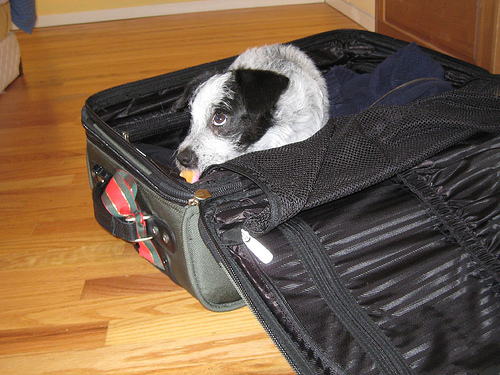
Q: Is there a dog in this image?
A: Yes, there is a dog.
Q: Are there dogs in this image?
A: Yes, there is a dog.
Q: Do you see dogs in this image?
A: Yes, there is a dog.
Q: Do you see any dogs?
A: Yes, there is a dog.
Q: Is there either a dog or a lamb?
A: Yes, there is a dog.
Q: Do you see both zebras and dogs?
A: No, there is a dog but no zebras.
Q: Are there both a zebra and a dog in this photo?
A: No, there is a dog but no zebras.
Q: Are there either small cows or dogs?
A: Yes, there is a small dog.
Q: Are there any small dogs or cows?
A: Yes, there is a small dog.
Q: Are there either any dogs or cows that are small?
A: Yes, the dog is small.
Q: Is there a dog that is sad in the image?
A: Yes, there is a sad dog.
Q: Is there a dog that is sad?
A: Yes, there is a dog that is sad.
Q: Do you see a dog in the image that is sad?
A: Yes, there is a dog that is sad.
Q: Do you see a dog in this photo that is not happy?
A: Yes, there is a sad dog.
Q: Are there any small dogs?
A: Yes, there is a small dog.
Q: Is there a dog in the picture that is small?
A: Yes, there is a dog that is small.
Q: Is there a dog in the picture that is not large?
A: Yes, there is a small dog.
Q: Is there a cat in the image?
A: No, there are no cats.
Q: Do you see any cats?
A: No, there are no cats.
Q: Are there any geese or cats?
A: No, there are no cats or geese.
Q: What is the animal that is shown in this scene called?
A: The animal is a dog.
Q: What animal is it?
A: The animal is a dog.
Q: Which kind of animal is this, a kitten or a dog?
A: That is a dog.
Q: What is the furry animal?
A: The animal is a dog.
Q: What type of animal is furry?
A: The animal is a dog.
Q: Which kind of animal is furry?
A: The animal is a dog.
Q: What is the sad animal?
A: The animal is a dog.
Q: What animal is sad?
A: The animal is a dog.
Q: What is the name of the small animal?
A: The animal is a dog.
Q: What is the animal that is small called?
A: The animal is a dog.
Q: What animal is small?
A: The animal is a dog.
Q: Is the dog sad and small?
A: Yes, the dog is sad and small.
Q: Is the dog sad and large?
A: No, the dog is sad but small.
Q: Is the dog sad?
A: Yes, the dog is sad.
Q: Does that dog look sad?
A: Yes, the dog is sad.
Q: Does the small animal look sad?
A: Yes, the dog is sad.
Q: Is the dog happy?
A: No, the dog is sad.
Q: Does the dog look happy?
A: No, the dog is sad.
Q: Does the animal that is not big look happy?
A: No, the dog is sad.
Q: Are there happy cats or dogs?
A: No, there is a dog but it is sad.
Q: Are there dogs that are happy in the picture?
A: No, there is a dog but it is sad.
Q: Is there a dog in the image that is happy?
A: No, there is a dog but it is sad.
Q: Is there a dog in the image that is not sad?
A: No, there is a dog but it is sad.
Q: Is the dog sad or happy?
A: The dog is sad.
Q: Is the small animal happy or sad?
A: The dog is sad.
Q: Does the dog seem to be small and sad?
A: Yes, the dog is small and sad.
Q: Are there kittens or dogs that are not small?
A: No, there is a dog but it is small.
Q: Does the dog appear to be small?
A: Yes, the dog is small.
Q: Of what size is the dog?
A: The dog is small.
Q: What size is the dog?
A: The dog is small.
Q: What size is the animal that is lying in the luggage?
A: The dog is small.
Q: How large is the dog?
A: The dog is small.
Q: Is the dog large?
A: No, the dog is small.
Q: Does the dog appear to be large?
A: No, the dog is small.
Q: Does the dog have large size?
A: No, the dog is small.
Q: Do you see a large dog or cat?
A: No, there is a dog but it is small.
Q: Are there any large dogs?
A: No, there is a dog but it is small.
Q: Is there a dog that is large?
A: No, there is a dog but it is small.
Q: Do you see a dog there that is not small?
A: No, there is a dog but it is small.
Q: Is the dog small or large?
A: The dog is small.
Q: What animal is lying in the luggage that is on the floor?
A: The dog is lying in the luggage.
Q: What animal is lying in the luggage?
A: The dog is lying in the luggage.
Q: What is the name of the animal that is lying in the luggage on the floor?
A: The animal is a dog.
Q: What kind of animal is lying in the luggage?
A: The animal is a dog.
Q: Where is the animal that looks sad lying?
A: The dog is lying in the luggage.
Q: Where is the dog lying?
A: The dog is lying in the luggage.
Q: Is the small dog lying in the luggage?
A: Yes, the dog is lying in the luggage.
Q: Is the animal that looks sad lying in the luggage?
A: Yes, the dog is lying in the luggage.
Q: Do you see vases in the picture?
A: No, there are no vases.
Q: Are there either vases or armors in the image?
A: No, there are no vases or armors.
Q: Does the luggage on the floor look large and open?
A: Yes, the luggage is large and open.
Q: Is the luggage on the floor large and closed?
A: No, the luggage is large but open.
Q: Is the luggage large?
A: Yes, the luggage is large.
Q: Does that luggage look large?
A: Yes, the luggage is large.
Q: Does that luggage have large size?
A: Yes, the luggage is large.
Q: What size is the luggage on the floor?
A: The luggage is large.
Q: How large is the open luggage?
A: The luggage is large.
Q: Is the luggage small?
A: No, the luggage is large.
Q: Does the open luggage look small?
A: No, the luggage is large.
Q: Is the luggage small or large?
A: The luggage is large.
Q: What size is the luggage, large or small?
A: The luggage is large.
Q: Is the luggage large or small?
A: The luggage is large.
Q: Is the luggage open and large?
A: Yes, the luggage is open and large.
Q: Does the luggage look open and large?
A: Yes, the luggage is open and large.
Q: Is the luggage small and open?
A: No, the luggage is open but large.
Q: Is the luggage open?
A: Yes, the luggage is open.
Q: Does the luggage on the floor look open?
A: Yes, the luggage is open.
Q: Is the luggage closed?
A: No, the luggage is open.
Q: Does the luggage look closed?
A: No, the luggage is open.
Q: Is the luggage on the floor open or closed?
A: The luggage is open.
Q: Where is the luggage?
A: The luggage is on the floor.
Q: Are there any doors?
A: Yes, there is a door.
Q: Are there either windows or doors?
A: Yes, there is a door.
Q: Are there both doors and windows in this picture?
A: No, there is a door but no windows.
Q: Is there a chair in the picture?
A: No, there are no chairs.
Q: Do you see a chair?
A: No, there are no chairs.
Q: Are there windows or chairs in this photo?
A: No, there are no chairs or windows.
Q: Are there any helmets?
A: No, there are no helmets.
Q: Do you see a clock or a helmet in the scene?
A: No, there are no helmets or clocks.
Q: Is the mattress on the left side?
A: Yes, the mattress is on the left of the image.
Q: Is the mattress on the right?
A: No, the mattress is on the left of the image.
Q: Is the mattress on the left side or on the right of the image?
A: The mattress is on the left of the image.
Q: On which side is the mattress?
A: The mattress is on the left of the image.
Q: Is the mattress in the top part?
A: Yes, the mattress is in the top of the image.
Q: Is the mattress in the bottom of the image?
A: No, the mattress is in the top of the image.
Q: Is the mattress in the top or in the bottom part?
A: The mattress is in the top of the image.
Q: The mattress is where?
A: The mattress is on the floor.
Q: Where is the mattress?
A: The mattress is on the floor.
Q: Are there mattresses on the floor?
A: Yes, there is a mattress on the floor.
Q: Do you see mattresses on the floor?
A: Yes, there is a mattress on the floor.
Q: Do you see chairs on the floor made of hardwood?
A: No, there is a mattress on the floor.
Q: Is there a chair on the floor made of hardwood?
A: No, there is a mattress on the floor.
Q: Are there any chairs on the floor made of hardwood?
A: No, there is a mattress on the floor.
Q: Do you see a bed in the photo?
A: No, there are no beds.